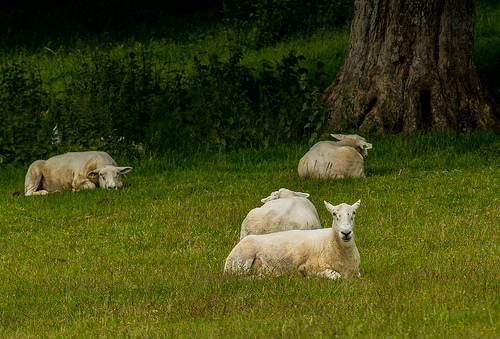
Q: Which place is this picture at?
A: It is at the field.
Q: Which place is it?
A: It is a field.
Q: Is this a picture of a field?
A: Yes, it is showing a field.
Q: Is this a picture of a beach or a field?
A: It is showing a field.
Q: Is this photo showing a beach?
A: No, the picture is showing a field.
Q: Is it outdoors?
A: Yes, it is outdoors.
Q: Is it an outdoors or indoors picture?
A: It is outdoors.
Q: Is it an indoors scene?
A: No, it is outdoors.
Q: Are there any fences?
A: No, there are no fences.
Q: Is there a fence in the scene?
A: No, there are no fences.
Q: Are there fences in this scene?
A: No, there are no fences.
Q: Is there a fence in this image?
A: No, there are no fences.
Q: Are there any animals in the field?
A: Yes, there is an animal in the field.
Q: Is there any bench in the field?
A: No, there is an animal in the field.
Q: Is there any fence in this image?
A: No, there are no fences.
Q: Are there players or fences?
A: No, there are no fences or players.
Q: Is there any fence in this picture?
A: No, there are no fences.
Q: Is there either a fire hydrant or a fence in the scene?
A: No, there are no fences or fire hydrants.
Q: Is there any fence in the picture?
A: No, there are no fences.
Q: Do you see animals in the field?
A: Yes, there is an animal in the field.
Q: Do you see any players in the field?
A: No, there is an animal in the field.